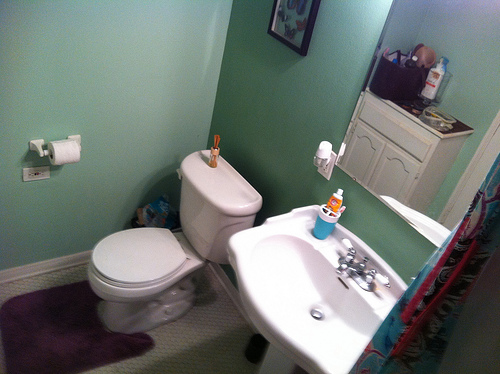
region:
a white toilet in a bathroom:
[91, 141, 263, 333]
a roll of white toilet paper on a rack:
[27, 133, 86, 165]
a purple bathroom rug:
[4, 278, 153, 372]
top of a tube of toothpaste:
[323, 183, 343, 214]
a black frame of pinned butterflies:
[266, 1, 322, 55]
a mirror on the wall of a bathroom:
[333, 0, 498, 250]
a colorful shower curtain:
[345, 143, 499, 370]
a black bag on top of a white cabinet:
[368, 48, 429, 100]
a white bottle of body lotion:
[421, 53, 446, 101]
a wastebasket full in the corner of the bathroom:
[129, 195, 185, 229]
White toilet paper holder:
[28, 133, 82, 156]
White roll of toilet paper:
[45, 137, 82, 166]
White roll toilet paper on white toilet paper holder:
[27, 134, 84, 165]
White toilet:
[83, 145, 262, 336]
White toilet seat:
[88, 225, 188, 287]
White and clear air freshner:
[312, 138, 332, 169]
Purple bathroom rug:
[1, 278, 157, 373]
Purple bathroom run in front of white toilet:
[1, 148, 263, 372]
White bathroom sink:
[226, 200, 410, 372]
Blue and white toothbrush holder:
[310, 200, 340, 242]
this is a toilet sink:
[84, 227, 212, 344]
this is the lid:
[96, 236, 172, 276]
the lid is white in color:
[123, 228, 160, 258]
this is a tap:
[330, 245, 387, 301]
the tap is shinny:
[338, 252, 380, 286]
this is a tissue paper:
[51, 141, 87, 163]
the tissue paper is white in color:
[53, 138, 73, 164]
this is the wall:
[66, 12, 158, 84]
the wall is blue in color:
[95, 30, 172, 92]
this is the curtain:
[411, 241, 473, 313]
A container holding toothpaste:
[315, 185, 348, 242]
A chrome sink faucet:
[335, 231, 390, 297]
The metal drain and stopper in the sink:
[305, 305, 324, 320]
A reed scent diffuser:
[205, 132, 224, 167]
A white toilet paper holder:
[27, 130, 87, 165]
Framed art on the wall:
[262, 0, 327, 65]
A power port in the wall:
[17, 161, 52, 186]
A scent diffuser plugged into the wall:
[312, 137, 332, 169]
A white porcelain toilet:
[78, 143, 263, 339]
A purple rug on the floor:
[2, 273, 160, 372]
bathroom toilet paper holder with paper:
[21, 131, 84, 182]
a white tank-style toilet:
[81, 141, 266, 334]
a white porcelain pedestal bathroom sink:
[228, 202, 413, 372]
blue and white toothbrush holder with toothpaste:
[307, 185, 347, 242]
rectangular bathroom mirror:
[331, 0, 497, 230]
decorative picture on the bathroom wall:
[262, 2, 322, 54]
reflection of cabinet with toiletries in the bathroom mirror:
[331, 35, 492, 220]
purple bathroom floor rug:
[4, 277, 163, 371]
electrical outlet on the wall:
[20, 163, 52, 178]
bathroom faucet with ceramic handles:
[328, 228, 392, 300]